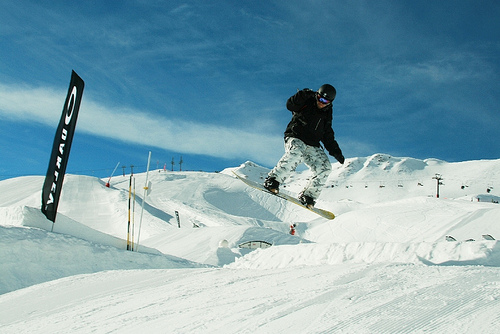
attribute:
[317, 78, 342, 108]
helmet — black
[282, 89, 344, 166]
jacket — black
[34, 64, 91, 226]
banner — black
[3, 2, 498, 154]
sky — blue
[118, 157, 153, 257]
poles — some